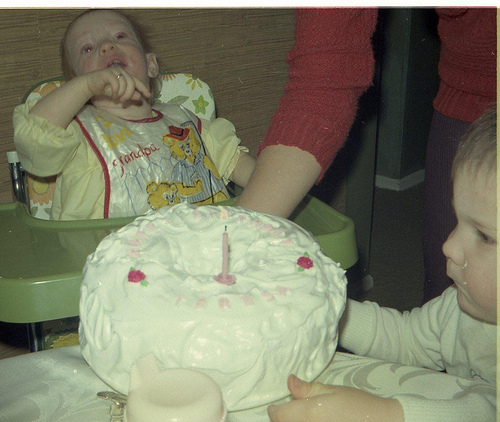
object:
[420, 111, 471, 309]
purple pants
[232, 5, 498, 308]
person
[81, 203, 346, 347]
icing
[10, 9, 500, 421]
both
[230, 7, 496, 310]
adult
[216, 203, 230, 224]
flame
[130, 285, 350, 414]
white cake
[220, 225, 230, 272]
pink candle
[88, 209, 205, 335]
white icing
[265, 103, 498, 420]
baby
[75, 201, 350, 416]
cake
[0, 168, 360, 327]
tray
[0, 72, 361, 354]
chair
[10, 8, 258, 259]
baby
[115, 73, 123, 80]
ring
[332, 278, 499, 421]
sweatshirt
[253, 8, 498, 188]
sweater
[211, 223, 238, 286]
candle